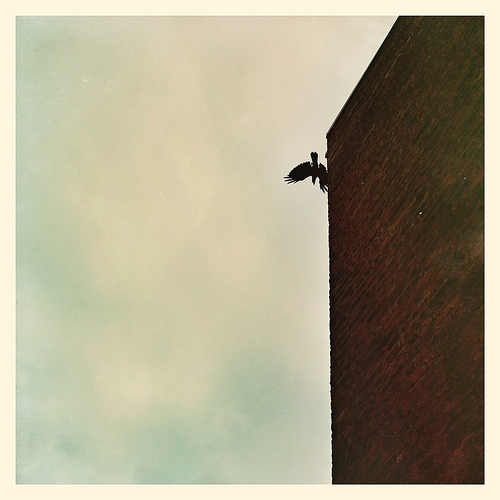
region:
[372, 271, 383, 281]
red brick on building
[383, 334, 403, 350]
red brick on building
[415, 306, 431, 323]
red brick on building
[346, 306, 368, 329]
red brick on building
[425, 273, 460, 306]
red brick on building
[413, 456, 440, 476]
red brick on building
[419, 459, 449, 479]
red brick on building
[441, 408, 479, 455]
red brick on building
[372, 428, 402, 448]
red brick on building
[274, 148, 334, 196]
sillhouete of bird in sky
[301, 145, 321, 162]
tail of bird in sky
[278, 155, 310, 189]
wing on airplane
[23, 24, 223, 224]
misty grey clouds in sky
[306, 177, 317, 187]
sillhouette of bird head in sky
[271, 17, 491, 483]
bird flying in sky next to building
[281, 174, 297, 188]
feathers on wing of bird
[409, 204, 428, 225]
white spot on side of building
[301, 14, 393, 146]
rooftop of building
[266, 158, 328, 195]
Bird flying close to a brown building.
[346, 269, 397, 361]
Bird flying close to a brown building.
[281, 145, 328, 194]
Bird flying next to a building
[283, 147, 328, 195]
Bird flying in the sky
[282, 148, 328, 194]
Bird falling from the sky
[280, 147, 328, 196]
Bird flying down from the sky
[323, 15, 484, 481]
tall windowless red brick building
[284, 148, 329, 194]
Underside of a bird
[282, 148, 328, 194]
Bird flying near a building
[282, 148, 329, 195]
medium sized bird in the sky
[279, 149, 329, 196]
Bird flapping its wings